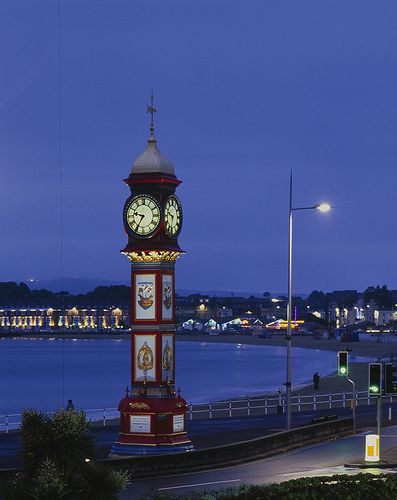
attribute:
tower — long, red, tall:
[108, 87, 207, 455]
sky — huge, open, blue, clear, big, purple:
[2, 5, 396, 294]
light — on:
[259, 151, 343, 377]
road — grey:
[14, 390, 396, 484]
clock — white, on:
[123, 191, 176, 237]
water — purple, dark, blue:
[2, 328, 308, 420]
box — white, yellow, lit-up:
[353, 432, 384, 463]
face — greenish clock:
[125, 191, 193, 246]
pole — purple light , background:
[292, 304, 300, 326]